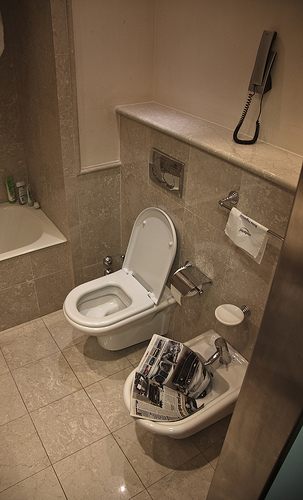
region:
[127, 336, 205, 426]
magazine inside a toilet bowl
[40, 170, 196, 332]
a white bathroom toilet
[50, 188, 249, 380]
a toilet with lid open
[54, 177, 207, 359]
a white toilet with lid open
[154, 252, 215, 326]
a roll of toilet papeer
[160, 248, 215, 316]
toilet paper on the wall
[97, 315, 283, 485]
a magazine in the sink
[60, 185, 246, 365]
a toilet in the bathroom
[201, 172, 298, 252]
toilet hanging on the wall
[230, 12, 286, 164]
a phone on the wall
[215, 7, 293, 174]
a silver phone on the wall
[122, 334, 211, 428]
a magazine sitting inside a bidet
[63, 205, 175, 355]
a white toilet with the lid up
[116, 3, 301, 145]
a painted wall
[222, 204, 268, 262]
a plastic bag hanging on a towel rod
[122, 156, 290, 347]
a tile wall behind a toilet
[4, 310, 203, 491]
a tile floor in a bathroom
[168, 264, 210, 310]
a roll of toilet paper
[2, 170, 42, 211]
toiletries on the edge of a bathtub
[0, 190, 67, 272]
a white bathtub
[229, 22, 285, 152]
a phone on the wall of a bathroom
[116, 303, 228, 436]
white toilet with magazine in it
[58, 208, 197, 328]
white toilet bowl with nothing in it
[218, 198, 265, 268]
white rag hanging on towel rack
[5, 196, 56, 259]
white ceramic bath tub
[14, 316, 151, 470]
tiled floor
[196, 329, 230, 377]
silver handle of sink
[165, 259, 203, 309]
toilet paper holder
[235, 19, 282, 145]
telephone hanging on the wall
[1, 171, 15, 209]
face cream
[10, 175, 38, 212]
shower gel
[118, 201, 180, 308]
the lid of the toilet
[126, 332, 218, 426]
a magazine in the toilet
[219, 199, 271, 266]
a cloth on the rack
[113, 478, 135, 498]
light shining on the floor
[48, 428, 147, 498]
a tile on the floor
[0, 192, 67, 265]
a white porcelain tub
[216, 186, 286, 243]
a metal towel rack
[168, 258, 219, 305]
a metal toilet paper dispenser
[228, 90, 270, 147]
a cord on the phone